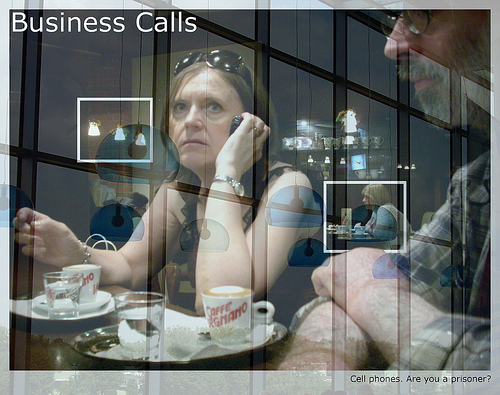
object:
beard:
[396, 24, 489, 134]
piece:
[116, 300, 276, 364]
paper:
[117, 303, 275, 363]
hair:
[158, 55, 278, 222]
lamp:
[306, 154, 314, 164]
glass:
[66, 54, 109, 85]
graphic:
[348, 371, 492, 383]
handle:
[252, 299, 275, 327]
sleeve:
[388, 312, 490, 371]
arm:
[191, 171, 311, 320]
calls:
[132, 8, 202, 35]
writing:
[10, 10, 125, 35]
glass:
[124, 308, 147, 335]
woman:
[10, 48, 315, 319]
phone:
[228, 113, 245, 137]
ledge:
[274, 146, 394, 162]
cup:
[294, 136, 313, 150]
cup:
[280, 136, 293, 148]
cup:
[321, 136, 333, 151]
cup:
[335, 136, 343, 148]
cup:
[372, 136, 385, 149]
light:
[86, 120, 102, 138]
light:
[111, 126, 128, 142]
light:
[132, 132, 149, 147]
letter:
[240, 300, 248, 313]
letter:
[234, 307, 242, 320]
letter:
[228, 310, 235, 324]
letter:
[218, 313, 227, 327]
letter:
[225, 300, 233, 311]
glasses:
[379, 9, 431, 38]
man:
[272, 10, 492, 370]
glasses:
[172, 48, 254, 87]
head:
[160, 50, 275, 170]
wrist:
[208, 163, 242, 187]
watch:
[210, 174, 245, 198]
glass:
[53, 280, 82, 302]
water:
[43, 281, 80, 310]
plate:
[66, 315, 288, 366]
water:
[116, 309, 162, 351]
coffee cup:
[198, 283, 274, 345]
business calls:
[11, 10, 197, 35]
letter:
[10, 10, 28, 35]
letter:
[45, 15, 58, 32]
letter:
[81, 15, 97, 34]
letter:
[134, 10, 154, 33]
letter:
[184, 15, 197, 32]